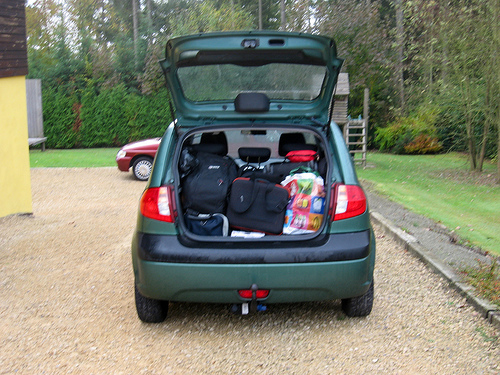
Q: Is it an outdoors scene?
A: Yes, it is outdoors.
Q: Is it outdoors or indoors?
A: It is outdoors.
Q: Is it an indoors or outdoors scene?
A: It is outdoors.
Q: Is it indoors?
A: No, it is outdoors.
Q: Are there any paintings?
A: No, there are no paintings.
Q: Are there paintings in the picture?
A: No, there are no paintings.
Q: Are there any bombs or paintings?
A: No, there are no paintings or bombs.